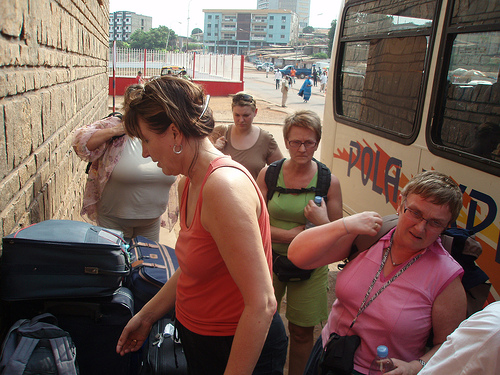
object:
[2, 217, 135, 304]
luggauge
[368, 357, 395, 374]
water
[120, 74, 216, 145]
hair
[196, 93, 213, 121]
clip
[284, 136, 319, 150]
eyeglasses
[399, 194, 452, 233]
sunglasses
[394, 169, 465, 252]
head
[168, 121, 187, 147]
ear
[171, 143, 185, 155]
earring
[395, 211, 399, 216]
earring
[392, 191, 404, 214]
ear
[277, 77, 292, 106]
people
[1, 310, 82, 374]
luggauges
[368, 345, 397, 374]
water bottle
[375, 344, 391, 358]
lid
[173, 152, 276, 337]
tank top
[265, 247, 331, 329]
shorts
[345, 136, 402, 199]
logo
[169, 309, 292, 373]
shorts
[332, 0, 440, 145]
window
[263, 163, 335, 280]
tank top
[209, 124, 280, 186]
shirt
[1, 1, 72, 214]
wall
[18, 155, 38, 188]
brick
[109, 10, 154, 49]
building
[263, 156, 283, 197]
straps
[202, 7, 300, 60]
building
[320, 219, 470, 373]
shirt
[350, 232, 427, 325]
lanyard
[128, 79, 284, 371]
passengers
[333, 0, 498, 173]
bus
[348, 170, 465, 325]
passengers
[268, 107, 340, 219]
passengers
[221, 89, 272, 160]
passengers